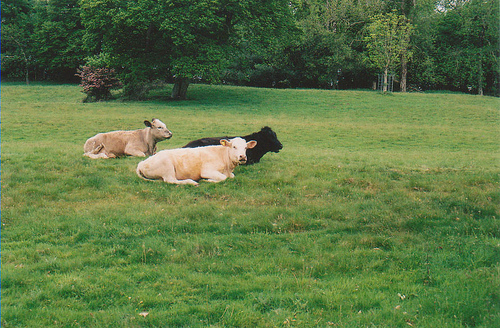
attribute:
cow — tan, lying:
[85, 115, 174, 161]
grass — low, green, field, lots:
[1, 82, 500, 327]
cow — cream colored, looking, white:
[138, 137, 258, 186]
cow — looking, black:
[182, 126, 283, 169]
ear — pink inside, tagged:
[144, 119, 153, 126]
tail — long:
[135, 164, 165, 184]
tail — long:
[82, 150, 113, 160]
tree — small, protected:
[365, 9, 416, 96]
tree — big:
[398, 2, 415, 94]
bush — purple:
[76, 63, 122, 102]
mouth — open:
[275, 145, 283, 155]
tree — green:
[152, 0, 253, 100]